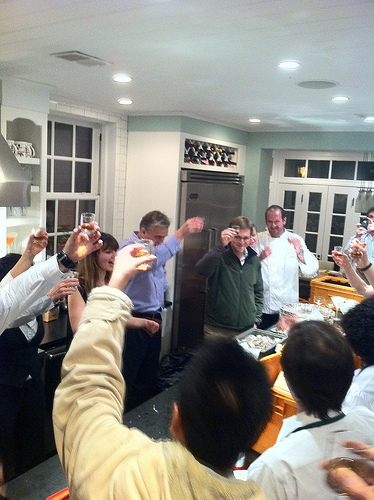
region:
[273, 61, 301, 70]
light in the ceiling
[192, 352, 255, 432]
a persons hair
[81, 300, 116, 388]
a beige jacket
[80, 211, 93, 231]
peson is holding a glass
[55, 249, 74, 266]
a watch on the persons wrist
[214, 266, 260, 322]
a green jacket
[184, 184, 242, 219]
a refrigerator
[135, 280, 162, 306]
man is wearing a blue shirt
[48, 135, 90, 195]
a window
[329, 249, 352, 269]
a persons hand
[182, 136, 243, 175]
white wine rack above the refrigerator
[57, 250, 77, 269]
a black wrist watch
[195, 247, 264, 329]
dark long sleeve zip up jacket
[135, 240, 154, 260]
shot glass in hand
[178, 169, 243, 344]
two door refrigerator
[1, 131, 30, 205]
stainless steel oven hood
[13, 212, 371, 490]
group of people raising glasses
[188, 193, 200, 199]
black logo on the door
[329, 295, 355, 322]
white frosted martini glasses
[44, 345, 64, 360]
dish washer handle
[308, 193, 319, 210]
pane of the door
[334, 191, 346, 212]
pane of the door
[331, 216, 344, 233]
pane of the door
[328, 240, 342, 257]
pane of the door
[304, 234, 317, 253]
pane of the door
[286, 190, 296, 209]
pane of the door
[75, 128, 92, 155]
pane of the door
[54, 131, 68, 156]
pane of the door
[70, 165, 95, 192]
pane of the door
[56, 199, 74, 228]
pane of the door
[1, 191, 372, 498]
A group of people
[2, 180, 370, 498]
People are holding shot glasses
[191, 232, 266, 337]
Person has a dark green jacket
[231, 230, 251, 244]
Person is wearing eyeglasses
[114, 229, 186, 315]
Man is wearing a blue dress shirt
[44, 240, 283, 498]
Person in the foreground is turned away from camera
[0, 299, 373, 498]
A table in the foreground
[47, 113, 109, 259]
Window in the background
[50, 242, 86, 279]
Person is wearing a wristwatch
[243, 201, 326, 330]
Person in the background is wearing a cooking outfit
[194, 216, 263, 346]
A man holding a glass.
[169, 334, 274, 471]
Back of a man's head.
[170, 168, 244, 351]
A stainless steel ice box.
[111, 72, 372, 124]
Lights on a ceiling.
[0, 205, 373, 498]
People making a toast.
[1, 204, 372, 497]
People raising their glasses.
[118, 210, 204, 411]
A man in a blue shirt.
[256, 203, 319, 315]
A man in a white shirt.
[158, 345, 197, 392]
A trash bag on the floor.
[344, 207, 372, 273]
A man taking as picture.